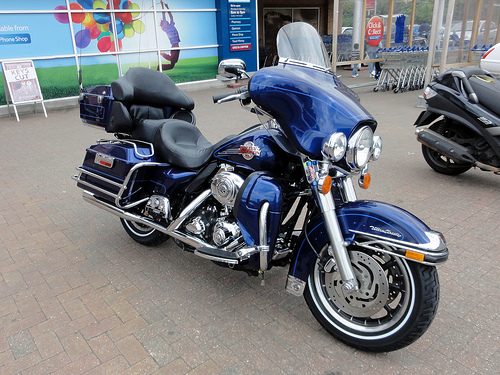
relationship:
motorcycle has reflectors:
[73, 21, 449, 356] [320, 171, 426, 263]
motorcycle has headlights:
[73, 21, 449, 356] [321, 125, 384, 175]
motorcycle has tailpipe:
[73, 21, 449, 356] [81, 189, 258, 260]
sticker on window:
[365, 15, 385, 48] [332, 0, 500, 74]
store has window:
[1, 0, 499, 116] [332, 0, 500, 74]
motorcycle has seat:
[73, 21, 449, 356] [106, 66, 237, 168]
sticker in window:
[365, 15, 385, 48] [332, 0, 500, 74]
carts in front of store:
[370, 41, 496, 92] [1, 0, 499, 116]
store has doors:
[1, 0, 499, 116] [261, 5, 320, 68]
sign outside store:
[2, 59, 51, 123] [1, 0, 499, 116]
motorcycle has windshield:
[73, 21, 449, 356] [275, 20, 335, 72]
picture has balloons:
[1, 0, 220, 109] [52, 2, 145, 56]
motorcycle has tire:
[73, 21, 449, 356] [304, 234, 440, 353]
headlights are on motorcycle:
[321, 125, 384, 175] [73, 21, 449, 356]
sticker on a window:
[365, 15, 385, 48] [332, 0, 500, 74]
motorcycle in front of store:
[73, 21, 449, 356] [1, 0, 499, 116]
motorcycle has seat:
[414, 42, 500, 179] [471, 72, 499, 114]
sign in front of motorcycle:
[2, 59, 51, 123] [73, 21, 449, 356]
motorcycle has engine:
[73, 21, 449, 356] [181, 163, 250, 247]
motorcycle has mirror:
[73, 21, 449, 356] [216, 57, 244, 81]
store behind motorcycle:
[1, 0, 499, 116] [73, 21, 449, 356]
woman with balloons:
[157, 2, 183, 74] [52, 2, 145, 56]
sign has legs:
[2, 59, 51, 123] [7, 104, 48, 122]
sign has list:
[227, 1, 253, 51] [229, 0, 253, 53]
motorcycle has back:
[73, 21, 449, 356] [78, 81, 117, 126]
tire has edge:
[304, 234, 440, 353] [391, 256, 442, 354]